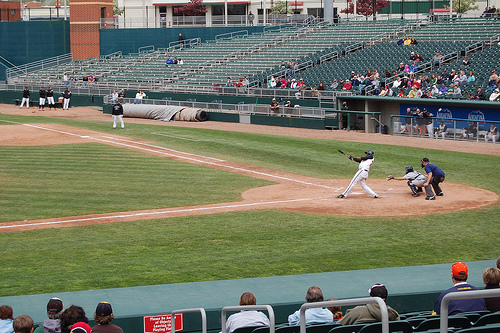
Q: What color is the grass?
A: Green.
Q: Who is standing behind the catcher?
A: The umpire.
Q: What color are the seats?
A: Green.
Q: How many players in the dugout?
A: Six.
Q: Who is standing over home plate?
A: The batter.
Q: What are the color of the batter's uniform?
A: Blue and White.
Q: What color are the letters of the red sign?
A: White.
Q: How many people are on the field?
A: 8.